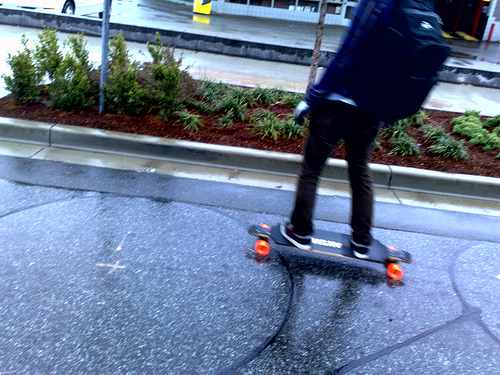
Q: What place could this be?
A: It is a road.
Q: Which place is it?
A: It is a road.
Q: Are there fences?
A: No, there are no fences.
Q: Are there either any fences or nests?
A: No, there are no fences or nests.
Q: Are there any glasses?
A: No, there are no glasses.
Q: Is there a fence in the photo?
A: No, there are no fences.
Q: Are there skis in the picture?
A: No, there are no skis.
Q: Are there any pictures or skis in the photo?
A: No, there are no skis or pictures.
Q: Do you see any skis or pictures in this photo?
A: No, there are no skis or pictures.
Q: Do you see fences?
A: No, there are no fences.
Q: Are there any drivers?
A: No, there are no drivers.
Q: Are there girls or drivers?
A: No, there are no drivers or girls.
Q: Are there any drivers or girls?
A: No, there are no drivers or girls.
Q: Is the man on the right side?
A: Yes, the man is on the right of the image.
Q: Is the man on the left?
A: No, the man is on the right of the image.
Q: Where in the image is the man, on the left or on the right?
A: The man is on the right of the image.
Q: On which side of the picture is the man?
A: The man is on the right of the image.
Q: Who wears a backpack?
A: The man wears a backpack.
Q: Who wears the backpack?
A: The man wears a backpack.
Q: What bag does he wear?
A: The man wears a backpack.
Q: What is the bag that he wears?
A: The bag is a backpack.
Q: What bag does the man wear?
A: The man wears a backpack.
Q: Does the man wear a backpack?
A: Yes, the man wears a backpack.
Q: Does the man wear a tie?
A: No, the man wears a backpack.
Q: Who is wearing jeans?
A: The man is wearing jeans.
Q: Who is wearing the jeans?
A: The man is wearing jeans.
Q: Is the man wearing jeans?
A: Yes, the man is wearing jeans.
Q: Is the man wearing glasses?
A: No, the man is wearing jeans.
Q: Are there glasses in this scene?
A: No, there are no glasses.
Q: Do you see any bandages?
A: No, there are no bandages.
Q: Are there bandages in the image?
A: No, there are no bandages.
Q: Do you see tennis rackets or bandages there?
A: No, there are no bandages or tennis rackets.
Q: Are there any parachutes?
A: No, there are no parachutes.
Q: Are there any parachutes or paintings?
A: No, there are no parachutes or paintings.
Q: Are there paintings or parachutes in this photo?
A: No, there are no parachutes or paintings.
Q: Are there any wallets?
A: No, there are no wallets.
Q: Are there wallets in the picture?
A: No, there are no wallets.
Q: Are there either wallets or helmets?
A: No, there are no wallets or helmets.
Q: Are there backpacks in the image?
A: Yes, there is a backpack.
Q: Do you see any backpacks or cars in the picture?
A: Yes, there is a backpack.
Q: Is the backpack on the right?
A: Yes, the backpack is on the right of the image.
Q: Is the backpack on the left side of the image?
A: No, the backpack is on the right of the image.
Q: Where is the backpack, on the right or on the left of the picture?
A: The backpack is on the right of the image.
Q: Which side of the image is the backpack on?
A: The backpack is on the right of the image.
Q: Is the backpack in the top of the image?
A: Yes, the backpack is in the top of the image.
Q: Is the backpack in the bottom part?
A: No, the backpack is in the top of the image.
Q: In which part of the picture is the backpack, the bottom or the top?
A: The backpack is in the top of the image.